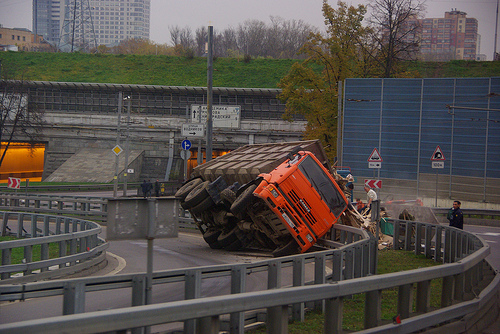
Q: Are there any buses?
A: No, there are no buses.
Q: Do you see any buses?
A: No, there are no buses.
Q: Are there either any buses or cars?
A: No, there are no buses or cars.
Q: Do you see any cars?
A: No, there are no cars.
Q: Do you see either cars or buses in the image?
A: No, there are no cars or buses.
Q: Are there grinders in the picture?
A: No, there are no grinders.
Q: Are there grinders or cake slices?
A: No, there are no grinders or cake slices.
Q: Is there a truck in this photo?
A: Yes, there is a truck.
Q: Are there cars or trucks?
A: Yes, there is a truck.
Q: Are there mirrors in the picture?
A: No, there are no mirrors.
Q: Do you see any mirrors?
A: No, there are no mirrors.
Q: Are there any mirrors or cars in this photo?
A: No, there are no mirrors or cars.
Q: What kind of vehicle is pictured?
A: The vehicle is a truck.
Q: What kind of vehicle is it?
A: The vehicle is a truck.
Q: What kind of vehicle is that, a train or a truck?
A: This is a truck.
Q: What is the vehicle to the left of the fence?
A: The vehicle is a truck.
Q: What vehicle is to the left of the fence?
A: The vehicle is a truck.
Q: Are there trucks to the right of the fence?
A: No, the truck is to the left of the fence.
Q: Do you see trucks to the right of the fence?
A: No, the truck is to the left of the fence.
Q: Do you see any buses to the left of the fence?
A: No, there is a truck to the left of the fence.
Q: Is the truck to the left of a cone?
A: No, the truck is to the left of the fence.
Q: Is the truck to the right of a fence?
A: No, the truck is to the left of a fence.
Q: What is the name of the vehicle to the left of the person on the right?
A: The vehicle is a truck.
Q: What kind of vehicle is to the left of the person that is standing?
A: The vehicle is a truck.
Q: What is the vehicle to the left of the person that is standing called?
A: The vehicle is a truck.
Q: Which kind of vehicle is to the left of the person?
A: The vehicle is a truck.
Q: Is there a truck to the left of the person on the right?
A: Yes, there is a truck to the left of the person.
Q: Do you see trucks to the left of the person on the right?
A: Yes, there is a truck to the left of the person.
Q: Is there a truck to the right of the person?
A: No, the truck is to the left of the person.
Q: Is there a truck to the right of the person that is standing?
A: No, the truck is to the left of the person.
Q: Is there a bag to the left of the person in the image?
A: No, there is a truck to the left of the person.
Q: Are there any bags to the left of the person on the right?
A: No, there is a truck to the left of the person.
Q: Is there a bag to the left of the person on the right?
A: No, there is a truck to the left of the person.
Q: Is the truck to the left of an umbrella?
A: No, the truck is to the left of the person.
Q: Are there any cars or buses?
A: No, there are no cars or buses.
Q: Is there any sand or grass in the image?
A: Yes, there is grass.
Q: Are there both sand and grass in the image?
A: No, there is grass but no sand.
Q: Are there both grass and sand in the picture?
A: No, there is grass but no sand.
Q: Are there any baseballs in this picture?
A: No, there are no baseballs.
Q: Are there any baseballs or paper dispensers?
A: No, there are no baseballs or paper dispensers.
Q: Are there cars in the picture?
A: No, there are no cars.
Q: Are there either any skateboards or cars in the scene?
A: No, there are no cars or skateboards.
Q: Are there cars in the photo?
A: No, there are no cars.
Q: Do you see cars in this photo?
A: No, there are no cars.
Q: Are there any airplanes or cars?
A: No, there are no cars or airplanes.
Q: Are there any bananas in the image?
A: No, there are no bananas.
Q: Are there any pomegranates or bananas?
A: No, there are no bananas or pomegranates.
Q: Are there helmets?
A: No, there are no helmets.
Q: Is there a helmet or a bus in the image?
A: No, there are no helmets or buses.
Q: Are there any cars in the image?
A: No, there are no cars.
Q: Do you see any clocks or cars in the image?
A: No, there are no cars or clocks.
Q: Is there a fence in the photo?
A: Yes, there is a fence.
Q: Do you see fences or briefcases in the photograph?
A: Yes, there is a fence.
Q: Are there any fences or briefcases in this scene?
A: Yes, there is a fence.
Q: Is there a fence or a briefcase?
A: Yes, there is a fence.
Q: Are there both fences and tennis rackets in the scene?
A: No, there is a fence but no rackets.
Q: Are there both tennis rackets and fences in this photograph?
A: No, there is a fence but no rackets.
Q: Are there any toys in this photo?
A: No, there are no toys.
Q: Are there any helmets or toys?
A: No, there are no toys or helmets.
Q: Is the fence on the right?
A: Yes, the fence is on the right of the image.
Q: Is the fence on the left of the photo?
A: No, the fence is on the right of the image.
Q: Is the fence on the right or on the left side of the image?
A: The fence is on the right of the image.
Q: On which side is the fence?
A: The fence is on the right of the image.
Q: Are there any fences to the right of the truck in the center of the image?
A: Yes, there is a fence to the right of the truck.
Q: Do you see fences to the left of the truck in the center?
A: No, the fence is to the right of the truck.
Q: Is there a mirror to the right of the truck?
A: No, there is a fence to the right of the truck.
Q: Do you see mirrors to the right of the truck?
A: No, there is a fence to the right of the truck.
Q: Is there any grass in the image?
A: Yes, there is grass.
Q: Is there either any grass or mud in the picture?
A: Yes, there is grass.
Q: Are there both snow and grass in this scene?
A: No, there is grass but no snow.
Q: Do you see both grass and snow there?
A: No, there is grass but no snow.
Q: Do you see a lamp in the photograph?
A: No, there are no lamps.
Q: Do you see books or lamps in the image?
A: No, there are no lamps or books.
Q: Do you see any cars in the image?
A: No, there are no cars.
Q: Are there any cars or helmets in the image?
A: No, there are no cars or helmets.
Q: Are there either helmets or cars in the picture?
A: No, there are no cars or helmets.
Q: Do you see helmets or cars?
A: No, there are no cars or helmets.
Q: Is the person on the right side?
A: Yes, the person is on the right of the image.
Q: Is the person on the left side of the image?
A: No, the person is on the right of the image.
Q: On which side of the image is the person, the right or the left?
A: The person is on the right of the image.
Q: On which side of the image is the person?
A: The person is on the right of the image.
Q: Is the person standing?
A: Yes, the person is standing.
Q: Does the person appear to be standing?
A: Yes, the person is standing.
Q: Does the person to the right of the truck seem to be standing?
A: Yes, the person is standing.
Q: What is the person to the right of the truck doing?
A: The person is standing.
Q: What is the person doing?
A: The person is standing.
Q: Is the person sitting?
A: No, the person is standing.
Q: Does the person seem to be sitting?
A: No, the person is standing.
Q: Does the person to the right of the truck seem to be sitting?
A: No, the person is standing.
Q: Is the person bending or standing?
A: The person is standing.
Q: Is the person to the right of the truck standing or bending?
A: The person is standing.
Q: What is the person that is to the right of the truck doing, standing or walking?
A: The person is standing.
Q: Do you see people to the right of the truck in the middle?
A: Yes, there is a person to the right of the truck.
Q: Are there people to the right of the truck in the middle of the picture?
A: Yes, there is a person to the right of the truck.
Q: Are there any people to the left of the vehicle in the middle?
A: No, the person is to the right of the truck.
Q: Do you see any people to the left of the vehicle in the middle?
A: No, the person is to the right of the truck.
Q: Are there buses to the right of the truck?
A: No, there is a person to the right of the truck.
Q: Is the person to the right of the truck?
A: Yes, the person is to the right of the truck.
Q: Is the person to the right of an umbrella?
A: No, the person is to the right of the truck.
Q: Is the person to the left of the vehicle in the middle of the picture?
A: No, the person is to the right of the truck.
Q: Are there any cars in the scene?
A: No, there are no cars.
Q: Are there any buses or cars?
A: No, there are no cars or buses.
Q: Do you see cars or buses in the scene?
A: No, there are no cars or buses.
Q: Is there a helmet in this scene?
A: No, there are no helmets.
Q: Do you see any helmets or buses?
A: No, there are no helmets or buses.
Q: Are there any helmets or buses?
A: No, there are no helmets or buses.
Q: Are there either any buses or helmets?
A: No, there are no helmets or buses.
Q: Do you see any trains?
A: No, there are no trains.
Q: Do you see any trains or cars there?
A: No, there are no trains or cars.